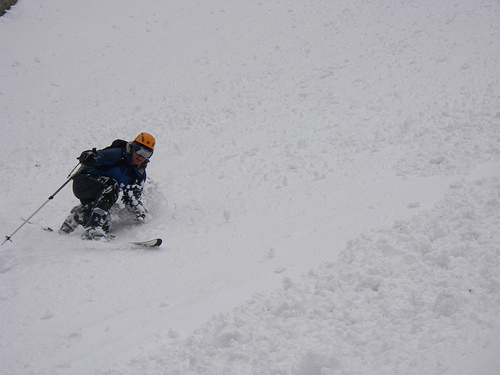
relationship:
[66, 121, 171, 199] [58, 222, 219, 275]
man on skis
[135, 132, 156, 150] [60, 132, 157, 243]
cap on man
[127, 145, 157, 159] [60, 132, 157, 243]
goggles on man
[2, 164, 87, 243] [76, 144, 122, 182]
pole in skier's hand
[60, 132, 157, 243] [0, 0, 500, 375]
man in snow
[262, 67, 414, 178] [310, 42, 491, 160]
snow covered mountain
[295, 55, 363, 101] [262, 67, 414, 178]
fluffy white snow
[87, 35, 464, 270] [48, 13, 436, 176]
scene during day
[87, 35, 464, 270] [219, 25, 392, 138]
scene in hillside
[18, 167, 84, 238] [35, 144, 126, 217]
black ski pole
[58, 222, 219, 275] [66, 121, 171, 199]
skis on man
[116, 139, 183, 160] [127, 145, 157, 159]
pair of goggles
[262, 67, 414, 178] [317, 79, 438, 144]
snow on ground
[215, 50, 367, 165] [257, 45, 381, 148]
place to ski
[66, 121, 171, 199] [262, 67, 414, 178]
person in snow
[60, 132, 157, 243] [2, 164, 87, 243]
man holding pole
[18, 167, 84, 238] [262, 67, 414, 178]
snowboard in snow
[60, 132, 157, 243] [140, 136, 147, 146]
man wearing cap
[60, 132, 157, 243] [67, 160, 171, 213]
man wearing snowsuit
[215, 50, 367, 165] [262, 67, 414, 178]
place of snow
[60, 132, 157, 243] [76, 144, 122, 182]
man wearing jacket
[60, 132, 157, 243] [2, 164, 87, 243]
man with pole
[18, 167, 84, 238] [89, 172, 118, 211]
black color pants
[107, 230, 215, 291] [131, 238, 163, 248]
white colored skis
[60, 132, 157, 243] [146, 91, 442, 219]
man coming down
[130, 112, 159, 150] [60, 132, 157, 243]
yellow helmet man